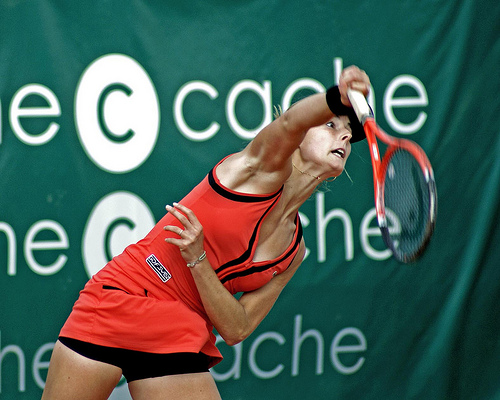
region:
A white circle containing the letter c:
[66, 44, 171, 184]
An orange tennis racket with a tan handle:
[335, 59, 456, 281]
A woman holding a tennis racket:
[324, 53, 458, 307]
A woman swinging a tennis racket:
[259, 53, 459, 293]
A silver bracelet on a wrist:
[178, 244, 213, 274]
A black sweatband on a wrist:
[318, 77, 360, 129]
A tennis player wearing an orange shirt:
[140, 128, 330, 367]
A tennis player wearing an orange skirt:
[54, 241, 233, 365]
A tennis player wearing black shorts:
[38, 301, 231, 398]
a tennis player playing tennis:
[33, 46, 461, 398]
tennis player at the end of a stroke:
[41, 62, 449, 390]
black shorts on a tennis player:
[32, 300, 226, 382]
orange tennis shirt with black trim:
[61, 151, 308, 368]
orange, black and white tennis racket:
[324, 63, 449, 271]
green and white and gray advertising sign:
[2, 36, 449, 381]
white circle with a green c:
[76, 50, 161, 175]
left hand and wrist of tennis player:
[153, 200, 215, 280]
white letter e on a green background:
[377, 73, 438, 139]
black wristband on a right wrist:
[312, 75, 354, 121]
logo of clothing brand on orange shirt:
[140, 250, 177, 288]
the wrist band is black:
[317, 68, 369, 150]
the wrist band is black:
[321, 80, 348, 127]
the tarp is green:
[166, 23, 272, 59]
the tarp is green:
[308, 309, 430, 346]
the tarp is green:
[32, 5, 204, 46]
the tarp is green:
[366, 272, 499, 343]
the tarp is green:
[37, 155, 117, 206]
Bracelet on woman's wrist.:
[175, 248, 215, 268]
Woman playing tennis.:
[37, 47, 445, 398]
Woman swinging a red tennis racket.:
[26, 58, 466, 398]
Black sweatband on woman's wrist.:
[319, 80, 348, 118]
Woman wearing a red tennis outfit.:
[27, 46, 413, 383]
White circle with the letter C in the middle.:
[61, 42, 167, 175]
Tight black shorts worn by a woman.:
[46, 324, 222, 393]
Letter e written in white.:
[5, 77, 70, 151]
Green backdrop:
[387, 285, 497, 393]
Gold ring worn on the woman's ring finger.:
[175, 222, 185, 237]